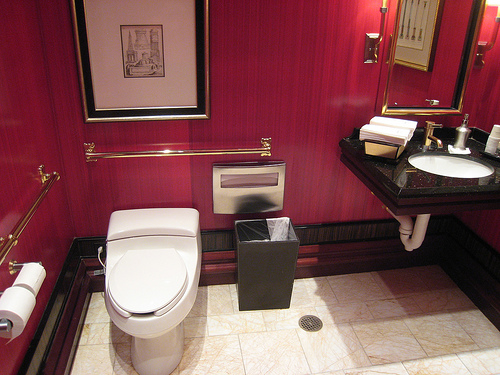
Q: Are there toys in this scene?
A: No, there are no toys.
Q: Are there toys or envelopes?
A: No, there are no toys or envelopes.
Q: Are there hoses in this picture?
A: No, there are no hoses.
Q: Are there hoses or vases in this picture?
A: No, there are no hoses or vases.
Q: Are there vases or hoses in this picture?
A: No, there are no hoses or vases.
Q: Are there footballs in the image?
A: No, there are no footballs.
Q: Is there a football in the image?
A: No, there are no footballs.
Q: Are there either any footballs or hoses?
A: No, there are no footballs or hoses.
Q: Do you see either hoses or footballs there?
A: No, there are no footballs or hoses.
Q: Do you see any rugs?
A: No, there are no rugs.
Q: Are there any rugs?
A: No, there are no rugs.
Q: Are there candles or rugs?
A: No, there are no rugs or candles.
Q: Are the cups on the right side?
A: Yes, the cups are on the right of the image.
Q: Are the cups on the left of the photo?
A: No, the cups are on the right of the image.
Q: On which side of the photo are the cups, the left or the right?
A: The cups are on the right of the image.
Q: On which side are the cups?
A: The cups are on the right of the image.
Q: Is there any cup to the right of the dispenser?
A: Yes, there are cups to the right of the dispenser.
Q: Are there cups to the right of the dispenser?
A: Yes, there are cups to the right of the dispenser.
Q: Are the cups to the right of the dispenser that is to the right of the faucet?
A: Yes, the cups are to the right of the dispenser.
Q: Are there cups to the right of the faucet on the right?
A: Yes, there are cups to the right of the faucet.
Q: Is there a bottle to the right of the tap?
A: No, there are cups to the right of the tap.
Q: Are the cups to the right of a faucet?
A: Yes, the cups are to the right of a faucet.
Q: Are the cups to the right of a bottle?
A: No, the cups are to the right of a faucet.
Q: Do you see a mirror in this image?
A: Yes, there is a mirror.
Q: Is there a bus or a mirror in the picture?
A: Yes, there is a mirror.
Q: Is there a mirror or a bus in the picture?
A: Yes, there is a mirror.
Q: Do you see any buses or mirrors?
A: Yes, there is a mirror.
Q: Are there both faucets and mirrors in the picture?
A: Yes, there are both a mirror and a faucet.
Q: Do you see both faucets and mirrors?
A: Yes, there are both a mirror and a faucet.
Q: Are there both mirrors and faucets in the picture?
A: Yes, there are both a mirror and a faucet.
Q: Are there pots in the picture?
A: No, there are no pots.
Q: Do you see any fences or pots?
A: No, there are no pots or fences.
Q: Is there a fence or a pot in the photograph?
A: No, there are no pots or fences.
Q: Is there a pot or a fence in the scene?
A: No, there are no pots or fences.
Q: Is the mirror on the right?
A: Yes, the mirror is on the right of the image.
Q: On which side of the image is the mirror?
A: The mirror is on the right of the image.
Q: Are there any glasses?
A: No, there are no glasses.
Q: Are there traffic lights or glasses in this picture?
A: No, there are no glasses or traffic lights.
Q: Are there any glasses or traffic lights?
A: No, there are no glasses or traffic lights.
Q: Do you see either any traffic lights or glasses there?
A: No, there are no glasses or traffic lights.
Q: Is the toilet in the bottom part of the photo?
A: Yes, the toilet is in the bottom of the image.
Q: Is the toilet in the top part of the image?
A: No, the toilet is in the bottom of the image.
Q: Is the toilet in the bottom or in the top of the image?
A: The toilet is in the bottom of the image.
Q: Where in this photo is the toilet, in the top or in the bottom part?
A: The toilet is in the bottom of the image.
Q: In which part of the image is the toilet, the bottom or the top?
A: The toilet is in the bottom of the image.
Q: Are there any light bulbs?
A: No, there are no light bulbs.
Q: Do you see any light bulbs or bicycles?
A: No, there are no light bulbs or bicycles.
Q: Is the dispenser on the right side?
A: Yes, the dispenser is on the right of the image.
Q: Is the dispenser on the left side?
A: No, the dispenser is on the right of the image.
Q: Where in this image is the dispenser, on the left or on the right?
A: The dispenser is on the right of the image.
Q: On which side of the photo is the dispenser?
A: The dispenser is on the right of the image.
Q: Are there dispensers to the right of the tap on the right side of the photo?
A: Yes, there is a dispenser to the right of the faucet.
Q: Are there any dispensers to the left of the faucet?
A: No, the dispenser is to the right of the faucet.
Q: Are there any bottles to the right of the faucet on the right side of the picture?
A: No, there is a dispenser to the right of the faucet.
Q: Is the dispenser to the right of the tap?
A: Yes, the dispenser is to the right of the tap.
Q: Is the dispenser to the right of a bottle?
A: No, the dispenser is to the right of the tap.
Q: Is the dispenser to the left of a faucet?
A: No, the dispenser is to the right of a faucet.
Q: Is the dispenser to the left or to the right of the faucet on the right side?
A: The dispenser is to the right of the faucet.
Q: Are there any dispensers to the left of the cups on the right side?
A: Yes, there is a dispenser to the left of the cups.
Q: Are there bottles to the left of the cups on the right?
A: No, there is a dispenser to the left of the cups.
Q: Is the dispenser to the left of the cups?
A: Yes, the dispenser is to the left of the cups.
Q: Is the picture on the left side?
A: Yes, the picture is on the left of the image.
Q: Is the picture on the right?
A: No, the picture is on the left of the image.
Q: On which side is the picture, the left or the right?
A: The picture is on the left of the image.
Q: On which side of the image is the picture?
A: The picture is on the left of the image.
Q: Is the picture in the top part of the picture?
A: Yes, the picture is in the top of the image.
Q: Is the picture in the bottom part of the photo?
A: No, the picture is in the top of the image.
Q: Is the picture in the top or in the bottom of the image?
A: The picture is in the top of the image.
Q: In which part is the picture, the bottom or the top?
A: The picture is in the top of the image.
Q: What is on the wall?
A: The picture is on the wall.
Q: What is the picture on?
A: The picture is on the wall.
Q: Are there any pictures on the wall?
A: Yes, there is a picture on the wall.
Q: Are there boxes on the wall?
A: No, there is a picture on the wall.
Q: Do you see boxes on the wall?
A: No, there is a picture on the wall.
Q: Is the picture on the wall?
A: Yes, the picture is on the wall.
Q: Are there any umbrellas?
A: No, there are no umbrellas.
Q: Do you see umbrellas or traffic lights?
A: No, there are no umbrellas or traffic lights.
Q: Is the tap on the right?
A: Yes, the tap is on the right of the image.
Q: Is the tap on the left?
A: No, the tap is on the right of the image.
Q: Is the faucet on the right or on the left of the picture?
A: The faucet is on the right of the image.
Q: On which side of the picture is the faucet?
A: The faucet is on the right of the image.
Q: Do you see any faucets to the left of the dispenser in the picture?
A: Yes, there is a faucet to the left of the dispenser.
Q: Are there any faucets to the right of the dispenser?
A: No, the faucet is to the left of the dispenser.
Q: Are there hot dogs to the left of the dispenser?
A: No, there is a faucet to the left of the dispenser.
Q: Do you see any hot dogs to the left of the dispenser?
A: No, there is a faucet to the left of the dispenser.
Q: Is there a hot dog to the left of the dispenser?
A: No, there is a faucet to the left of the dispenser.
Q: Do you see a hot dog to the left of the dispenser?
A: No, there is a faucet to the left of the dispenser.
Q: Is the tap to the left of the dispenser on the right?
A: Yes, the tap is to the left of the dispenser.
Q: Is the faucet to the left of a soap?
A: No, the faucet is to the left of the dispenser.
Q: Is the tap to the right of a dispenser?
A: No, the tap is to the left of a dispenser.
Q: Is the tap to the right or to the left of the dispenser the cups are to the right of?
A: The tap is to the left of the dispenser.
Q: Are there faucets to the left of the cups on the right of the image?
A: Yes, there is a faucet to the left of the cups.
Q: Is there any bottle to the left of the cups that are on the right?
A: No, there is a faucet to the left of the cups.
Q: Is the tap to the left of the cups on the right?
A: Yes, the tap is to the left of the cups.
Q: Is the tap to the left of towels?
A: No, the tap is to the left of the cups.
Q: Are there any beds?
A: No, there are no beds.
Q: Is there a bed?
A: No, there are no beds.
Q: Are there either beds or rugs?
A: No, there are no beds or rugs.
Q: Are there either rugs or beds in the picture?
A: No, there are no beds or rugs.